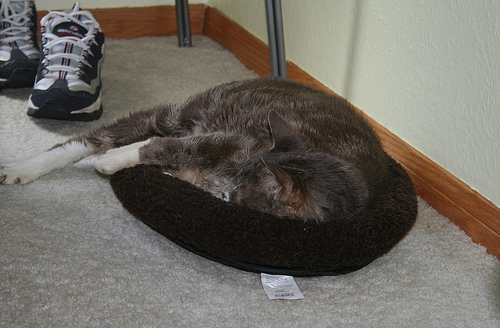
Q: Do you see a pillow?
A: No, there are no pillows.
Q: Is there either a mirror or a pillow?
A: No, there are no pillows or mirrors.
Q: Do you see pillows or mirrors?
A: No, there are no pillows or mirrors.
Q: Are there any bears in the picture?
A: No, there are no bears.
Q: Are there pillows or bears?
A: No, there are no bears or pillows.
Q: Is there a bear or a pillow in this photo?
A: No, there are no bears or pillows.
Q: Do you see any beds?
A: Yes, there is a bed.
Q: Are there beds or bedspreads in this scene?
A: Yes, there is a bed.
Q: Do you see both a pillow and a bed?
A: No, there is a bed but no pillows.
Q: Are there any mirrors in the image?
A: No, there are no mirrors.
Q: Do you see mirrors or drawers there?
A: No, there are no mirrors or drawers.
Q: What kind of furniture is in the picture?
A: The furniture is a bed.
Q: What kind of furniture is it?
A: The piece of furniture is a bed.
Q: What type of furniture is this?
A: That is a bed.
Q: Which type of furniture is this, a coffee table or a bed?
A: That is a bed.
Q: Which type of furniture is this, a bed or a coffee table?
A: That is a bed.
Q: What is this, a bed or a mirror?
A: This is a bed.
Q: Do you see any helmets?
A: No, there are no helmets.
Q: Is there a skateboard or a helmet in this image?
A: No, there are no helmets or skateboards.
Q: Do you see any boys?
A: No, there are no boys.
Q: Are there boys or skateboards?
A: No, there are no boys or skateboards.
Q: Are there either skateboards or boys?
A: No, there are no boys or skateboards.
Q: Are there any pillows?
A: No, there are no pillows.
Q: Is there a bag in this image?
A: No, there are no bags.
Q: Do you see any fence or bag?
A: No, there are no bags or fences.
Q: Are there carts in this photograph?
A: No, there are no carts.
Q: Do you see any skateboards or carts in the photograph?
A: No, there are no carts or skateboards.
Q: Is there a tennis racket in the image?
A: No, there are no rackets.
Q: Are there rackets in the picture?
A: No, there are no rackets.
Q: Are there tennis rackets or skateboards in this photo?
A: No, there are no tennis rackets or skateboards.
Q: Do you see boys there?
A: No, there are no boys.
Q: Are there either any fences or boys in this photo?
A: No, there are no boys or fences.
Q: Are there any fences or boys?
A: No, there are no boys or fences.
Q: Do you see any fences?
A: No, there are no fences.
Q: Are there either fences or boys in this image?
A: No, there are no fences or boys.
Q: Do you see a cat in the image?
A: Yes, there is a cat.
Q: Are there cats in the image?
A: Yes, there is a cat.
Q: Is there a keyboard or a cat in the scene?
A: Yes, there is a cat.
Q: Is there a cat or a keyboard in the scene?
A: Yes, there is a cat.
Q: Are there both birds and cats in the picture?
A: No, there is a cat but no birds.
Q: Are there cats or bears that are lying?
A: Yes, the cat is lying.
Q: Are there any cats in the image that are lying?
A: Yes, there is a cat that is lying.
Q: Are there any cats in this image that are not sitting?
A: Yes, there is a cat that is lying.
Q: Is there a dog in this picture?
A: No, there are no dogs.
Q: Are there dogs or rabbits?
A: No, there are no dogs or rabbits.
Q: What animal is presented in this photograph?
A: The animal is a cat.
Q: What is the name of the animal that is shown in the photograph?
A: The animal is a cat.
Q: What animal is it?
A: The animal is a cat.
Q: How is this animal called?
A: This is a cat.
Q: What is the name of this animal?
A: This is a cat.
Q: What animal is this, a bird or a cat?
A: This is a cat.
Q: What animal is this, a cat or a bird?
A: This is a cat.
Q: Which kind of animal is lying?
A: The animal is a cat.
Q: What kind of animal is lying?
A: The animal is a cat.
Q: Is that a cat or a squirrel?
A: That is a cat.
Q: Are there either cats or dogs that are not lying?
A: No, there is a cat but it is lying.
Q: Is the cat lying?
A: Yes, the cat is lying.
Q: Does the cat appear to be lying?
A: Yes, the cat is lying.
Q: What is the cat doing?
A: The cat is lying.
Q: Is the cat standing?
A: No, the cat is lying.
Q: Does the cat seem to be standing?
A: No, the cat is lying.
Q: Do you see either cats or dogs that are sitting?
A: No, there is a cat but it is lying.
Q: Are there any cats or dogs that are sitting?
A: No, there is a cat but it is lying.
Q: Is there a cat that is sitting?
A: No, there is a cat but it is lying.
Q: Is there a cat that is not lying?
A: No, there is a cat but it is lying.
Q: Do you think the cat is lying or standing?
A: The cat is lying.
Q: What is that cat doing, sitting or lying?
A: The cat is lying.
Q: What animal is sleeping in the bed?
A: The cat is sleeping in the bed.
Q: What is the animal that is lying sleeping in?
A: The cat is sleeping in the bed.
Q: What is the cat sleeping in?
A: The cat is sleeping in the bed.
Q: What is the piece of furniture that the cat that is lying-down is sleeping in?
A: The piece of furniture is a bed.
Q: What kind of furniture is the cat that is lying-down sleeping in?
A: The cat is sleeping in the bed.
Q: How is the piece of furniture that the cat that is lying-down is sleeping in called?
A: The piece of furniture is a bed.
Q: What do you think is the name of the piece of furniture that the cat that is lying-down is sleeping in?
A: The piece of furniture is a bed.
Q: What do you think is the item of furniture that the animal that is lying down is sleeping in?
A: The piece of furniture is a bed.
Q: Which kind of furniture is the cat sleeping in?
A: The cat is sleeping in the bed.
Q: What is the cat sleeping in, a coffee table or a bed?
A: The cat is sleeping in a bed.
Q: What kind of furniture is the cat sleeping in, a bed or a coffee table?
A: The cat is sleeping in a bed.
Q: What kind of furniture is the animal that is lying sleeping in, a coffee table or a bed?
A: The cat is sleeping in a bed.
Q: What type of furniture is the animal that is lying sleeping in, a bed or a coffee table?
A: The cat is sleeping in a bed.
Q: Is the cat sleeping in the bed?
A: Yes, the cat is sleeping in the bed.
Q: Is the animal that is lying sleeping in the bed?
A: Yes, the cat is sleeping in the bed.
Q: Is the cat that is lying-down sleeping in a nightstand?
A: No, the cat is sleeping in the bed.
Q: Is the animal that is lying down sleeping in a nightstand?
A: No, the cat is sleeping in the bed.